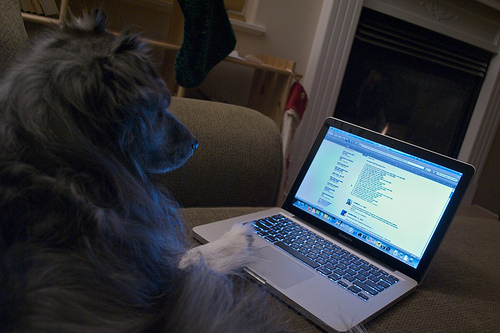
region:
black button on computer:
[356, 290, 369, 302]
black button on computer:
[346, 283, 361, 295]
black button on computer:
[339, 280, 349, 288]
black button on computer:
[327, 271, 342, 282]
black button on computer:
[316, 265, 331, 275]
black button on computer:
[353, 278, 377, 296]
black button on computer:
[273, 238, 317, 269]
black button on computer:
[387, 273, 399, 283]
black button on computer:
[381, 273, 395, 284]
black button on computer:
[374, 278, 389, 290]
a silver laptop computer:
[188, 113, 473, 329]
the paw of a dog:
[220, 222, 255, 261]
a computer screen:
[293, 126, 460, 267]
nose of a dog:
[189, 137, 199, 148]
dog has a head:
[7, 16, 200, 175]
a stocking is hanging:
[283, 78, 309, 173]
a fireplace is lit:
[327, 0, 489, 195]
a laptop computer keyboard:
[245, 211, 397, 305]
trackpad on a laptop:
[243, 246, 310, 289]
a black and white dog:
[3, 19, 260, 332]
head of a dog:
[40, 40, 207, 177]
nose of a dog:
[179, 125, 205, 153]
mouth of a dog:
[163, 111, 208, 191]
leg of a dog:
[215, 214, 259, 259]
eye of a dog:
[131, 88, 180, 123]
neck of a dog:
[3, 113, 138, 205]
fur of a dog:
[65, 177, 175, 271]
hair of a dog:
[75, 30, 157, 87]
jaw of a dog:
[143, 148, 179, 178]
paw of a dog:
[225, 220, 267, 260]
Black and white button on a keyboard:
[346, 283, 361, 293]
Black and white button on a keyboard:
[361, 273, 388, 299]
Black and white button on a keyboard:
[354, 255, 376, 280]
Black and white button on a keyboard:
[342, 262, 359, 282]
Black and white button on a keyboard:
[315, 256, 342, 280]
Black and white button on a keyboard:
[329, 244, 343, 257]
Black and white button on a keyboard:
[307, 234, 320, 248]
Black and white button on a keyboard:
[294, 238, 324, 269]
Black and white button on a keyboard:
[278, 211, 305, 226]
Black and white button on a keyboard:
[268, 216, 308, 258]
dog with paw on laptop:
[1, 15, 458, 332]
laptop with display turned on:
[193, 113, 475, 327]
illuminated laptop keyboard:
[242, 207, 400, 300]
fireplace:
[321, 13, 493, 220]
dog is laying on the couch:
[2, 15, 284, 323]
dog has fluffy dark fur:
[5, 15, 251, 327]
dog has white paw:
[183, 218, 255, 274]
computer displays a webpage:
[293, 114, 475, 276]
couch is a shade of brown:
[3, 18, 280, 325]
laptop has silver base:
[185, 110, 452, 331]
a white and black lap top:
[189, 115, 478, 332]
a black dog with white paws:
[4, 6, 287, 332]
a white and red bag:
[279, 75, 312, 183]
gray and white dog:
[37, 42, 198, 307]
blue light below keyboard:
[252, 223, 366, 277]